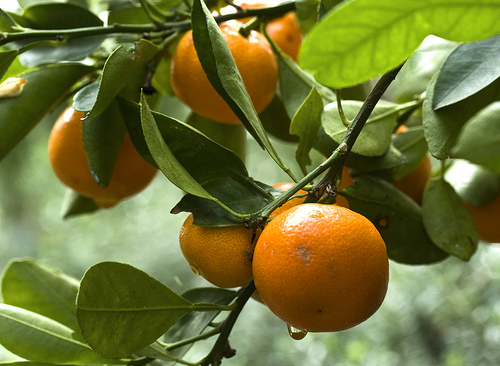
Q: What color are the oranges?
A: Orange.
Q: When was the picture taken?
A: Daytime.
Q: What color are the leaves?
A: Green.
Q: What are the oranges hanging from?
A: The tree.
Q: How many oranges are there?
A: Eight.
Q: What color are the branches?
A: Green and brown.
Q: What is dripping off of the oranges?
A: Water.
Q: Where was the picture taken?
A: In an orchard.